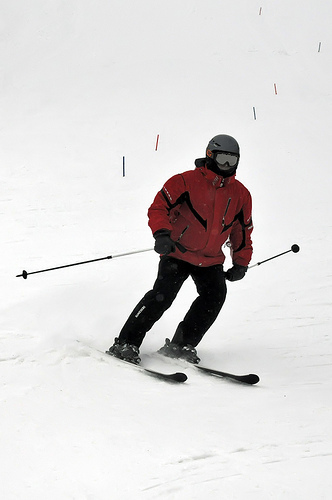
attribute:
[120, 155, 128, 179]
stick — blue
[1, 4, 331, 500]
snow — white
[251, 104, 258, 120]
stick — blue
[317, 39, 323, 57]
stick — blue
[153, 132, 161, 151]
stick — red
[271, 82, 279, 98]
stick — red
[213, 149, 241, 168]
goggles — red, black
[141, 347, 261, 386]
ski — black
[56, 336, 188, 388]
ski — black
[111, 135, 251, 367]
skier — skiing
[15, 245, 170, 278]
pole — white, black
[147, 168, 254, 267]
coat — red, black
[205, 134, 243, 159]
helmet — black, gray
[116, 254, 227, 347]
pants — black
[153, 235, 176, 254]
glove — black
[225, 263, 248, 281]
glove — black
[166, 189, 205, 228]
stripe — black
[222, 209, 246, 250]
stripe — black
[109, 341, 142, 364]
boot — black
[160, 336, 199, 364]
boot — black